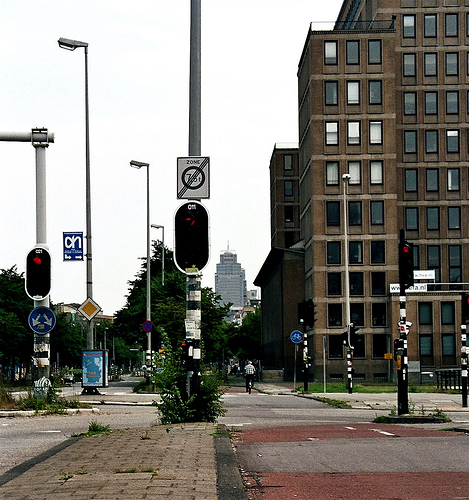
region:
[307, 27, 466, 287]
the wall is brown in colour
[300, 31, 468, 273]
the house has windows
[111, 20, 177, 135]
the sky is white in colour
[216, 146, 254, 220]
the sky is cloudy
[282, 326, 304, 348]
the sign is blue in colour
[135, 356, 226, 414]
the bush is green in colour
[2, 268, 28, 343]
the tree is green in colour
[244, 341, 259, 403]
a man is cycling the bike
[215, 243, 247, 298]
the wall is white in colour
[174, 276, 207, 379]
the post is black with white posters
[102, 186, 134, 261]
this is the sky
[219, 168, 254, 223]
the sky has clouds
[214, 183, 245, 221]
the clouds are white in color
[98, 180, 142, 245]
the clouds are big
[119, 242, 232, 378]
this is a tree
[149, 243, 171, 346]
the tree is tall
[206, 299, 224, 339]
the leaves are green in color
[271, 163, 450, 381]
this is a building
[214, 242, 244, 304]
the building is tall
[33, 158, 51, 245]
this is a pole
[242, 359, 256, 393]
A person riding a bicycle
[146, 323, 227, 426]
Green plants growing around a pole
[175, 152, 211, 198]
A white sign on the pole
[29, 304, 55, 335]
A blue circular sign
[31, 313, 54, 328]
Two white arrows on the sign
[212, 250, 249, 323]
A tall building in the distance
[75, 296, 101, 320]
A white and yellow diamond shaped sign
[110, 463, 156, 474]
Grass growing through cracks in the sidewalk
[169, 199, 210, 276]
A black traffic signal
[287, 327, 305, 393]
A blue sign on a pole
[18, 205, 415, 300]
Traffic signals indicating stop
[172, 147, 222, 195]
Sign board displaying caution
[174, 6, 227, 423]
Iron pole holding the traffic signal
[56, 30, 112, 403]
A tall light post with a big light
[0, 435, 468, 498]
Pedestrian walk beside the road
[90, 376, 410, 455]
Inter-junction of more than one road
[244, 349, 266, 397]
A man is riding his bike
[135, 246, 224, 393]
Trees with green leaves are present on both sides of the road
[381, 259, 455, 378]
Sign board displaying its business name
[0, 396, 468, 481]
Road seems to be empty without vehicle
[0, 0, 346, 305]
light in daytime sky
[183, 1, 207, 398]
gray metal pole in city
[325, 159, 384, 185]
windows with white curtains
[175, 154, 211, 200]
sign with circle on pole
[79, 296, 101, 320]
yellow and white sign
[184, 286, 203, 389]
stickers on metal pole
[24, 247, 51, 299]
glowing red of traffic light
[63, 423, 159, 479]
weeds growing in cement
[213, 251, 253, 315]
city building on horizon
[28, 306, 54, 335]
two white arrows on sign